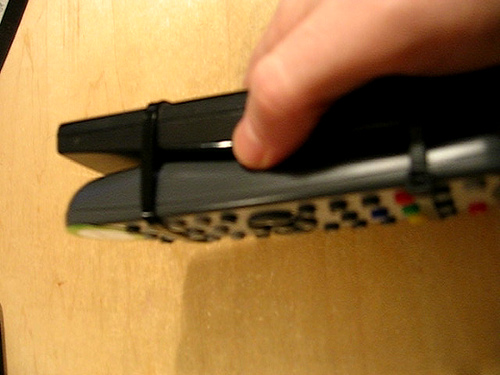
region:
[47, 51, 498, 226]
two black remote controls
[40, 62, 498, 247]
two black remote control together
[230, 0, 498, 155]
right hand holding two black remote controls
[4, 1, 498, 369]
brown wooden table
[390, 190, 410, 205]
red button in front control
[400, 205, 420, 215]
green button in front control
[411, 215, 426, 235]
yellow button in front control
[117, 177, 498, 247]
bunch of buttons in black and grey remote control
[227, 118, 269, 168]
thumbnail in right hand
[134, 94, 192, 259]
league that holds two controls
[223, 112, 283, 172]
thumbnail on finger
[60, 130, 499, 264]
Remote for electronic device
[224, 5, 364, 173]
finger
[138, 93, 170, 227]
fasteners for remote to block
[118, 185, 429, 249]
keys on the remote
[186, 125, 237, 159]
coin between remote and block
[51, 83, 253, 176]
block that remote is fastened to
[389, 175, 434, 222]
red, yellow and green buttons on remote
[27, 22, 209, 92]
wooden background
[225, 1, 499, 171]
hand holding remote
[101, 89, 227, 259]
remote in person's hand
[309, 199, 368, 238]
buttons on remote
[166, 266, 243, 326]
shadow on the table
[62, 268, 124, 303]
light brown table below remote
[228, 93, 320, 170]
thumb of the person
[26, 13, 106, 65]
lines on the table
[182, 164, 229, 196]
black part of remote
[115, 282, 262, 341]
light and dark table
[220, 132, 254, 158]
nail on the thumb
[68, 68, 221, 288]
two different remotes in hand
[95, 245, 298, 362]
Surface of wooden table.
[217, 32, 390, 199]
Thumb on right hand.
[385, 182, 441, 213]
Red button on device.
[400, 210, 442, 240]
Yellow button on device.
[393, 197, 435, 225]
Green buttons on device.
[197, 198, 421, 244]
Multiple black buttons on device.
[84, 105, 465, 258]
Remote control being held in hand.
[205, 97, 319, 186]
Finger nail on thumb.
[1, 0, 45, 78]
Black rim on table.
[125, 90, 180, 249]
Black plastic attaching devices together.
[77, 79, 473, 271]
remote controls in person's hand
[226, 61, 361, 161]
thumb on remote control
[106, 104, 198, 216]
band around remote controls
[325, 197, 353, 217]
button on remote control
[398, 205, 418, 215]
button on remote control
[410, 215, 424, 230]
button on remote control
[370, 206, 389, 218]
button on remote control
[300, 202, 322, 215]
button on remote control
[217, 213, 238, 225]
button on remote control